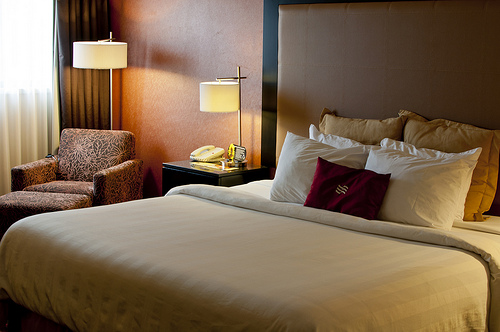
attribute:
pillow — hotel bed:
[262, 123, 471, 238]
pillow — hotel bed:
[271, 111, 482, 237]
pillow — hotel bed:
[263, 110, 484, 245]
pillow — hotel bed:
[270, 103, 484, 230]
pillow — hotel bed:
[272, 98, 483, 252]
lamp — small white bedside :
[192, 50, 256, 170]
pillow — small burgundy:
[295, 150, 403, 226]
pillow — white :
[274, 123, 482, 233]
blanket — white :
[10, 190, 483, 326]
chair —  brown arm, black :
[8, 112, 143, 215]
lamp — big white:
[59, 23, 134, 130]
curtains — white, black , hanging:
[1, 2, 62, 190]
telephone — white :
[184, 139, 227, 165]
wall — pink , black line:
[121, 10, 258, 170]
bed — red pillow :
[0, 104, 484, 326]